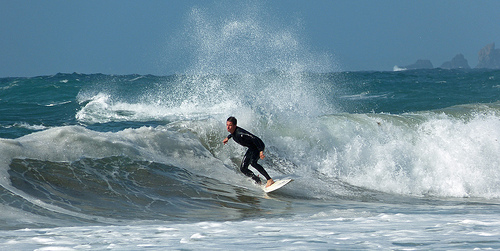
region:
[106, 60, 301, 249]
a man is surfing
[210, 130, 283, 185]
the suit is black in colour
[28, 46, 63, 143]
the water is greenish in colour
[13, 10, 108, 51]
the sky is blue in colour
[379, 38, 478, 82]
the mountains are on the horizon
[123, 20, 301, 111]
the water is raised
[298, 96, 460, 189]
the wave is white in colour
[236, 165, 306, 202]
the surfing board is white in colour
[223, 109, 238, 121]
the hair is black in colour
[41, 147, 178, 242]
the water is brown in colour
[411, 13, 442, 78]
There is a light blue sky that is in the distance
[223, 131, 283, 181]
This man is wearing a black wetsuit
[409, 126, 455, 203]
There is some high surf here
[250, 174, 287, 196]
There is a white surfboard that is present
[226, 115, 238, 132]
This man has a brown head of hair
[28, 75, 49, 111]
There is a bright blue color in the water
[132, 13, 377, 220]
Jackson Mingus took this photo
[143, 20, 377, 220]
This photo was taken in California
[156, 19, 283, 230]
This photo was taken in San Francisco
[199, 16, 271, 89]
This is a white spray of water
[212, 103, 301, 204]
surfer on a surf board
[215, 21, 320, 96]
white spray from the waves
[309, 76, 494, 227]
white foam from breaking waves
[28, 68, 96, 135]
choppy water in the ocean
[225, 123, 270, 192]
black wet suit on a surfer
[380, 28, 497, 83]
rocky structures in the distance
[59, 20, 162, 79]
blue sky on the horizon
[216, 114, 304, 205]
man surfing barefoot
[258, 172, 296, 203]
white surf board in the sea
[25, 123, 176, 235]
waves swelling to break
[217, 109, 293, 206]
Man on a skateboard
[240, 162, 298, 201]
Man riding a white skateboard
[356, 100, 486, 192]
Waves crashing in the ocean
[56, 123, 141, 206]
Waves crashing in the ocean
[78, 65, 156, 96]
Waves crashing in the ocean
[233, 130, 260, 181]
Man wearing a black wetsuit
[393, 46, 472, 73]
Mountains behind the ocean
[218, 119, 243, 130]
Man with black hair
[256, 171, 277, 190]
man barefoot on a skateboard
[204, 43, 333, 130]
Water spraying from waves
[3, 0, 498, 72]
blue of daytime sky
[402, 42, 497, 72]
rocks on water horizon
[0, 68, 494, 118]
surface of rough water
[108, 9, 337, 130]
water spray in the air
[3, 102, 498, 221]
front of crashing wave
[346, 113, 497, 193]
white water of crashed wave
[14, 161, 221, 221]
sea foam on wave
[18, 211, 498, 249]
white sea foam on surface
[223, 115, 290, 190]
man on white surfboard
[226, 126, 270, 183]
black wetsuit on man